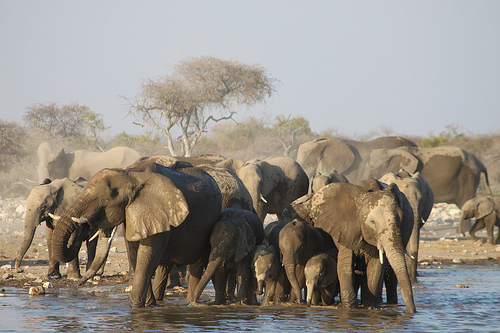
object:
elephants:
[289, 178, 420, 314]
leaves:
[157, 95, 173, 104]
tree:
[115, 55, 287, 158]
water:
[4, 262, 500, 333]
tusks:
[70, 216, 91, 226]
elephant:
[50, 160, 224, 307]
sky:
[0, 0, 500, 147]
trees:
[17, 101, 114, 143]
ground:
[0, 169, 500, 288]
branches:
[124, 113, 168, 132]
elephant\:
[191, 207, 266, 307]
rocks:
[25, 282, 49, 298]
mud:
[418, 258, 500, 268]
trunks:
[165, 126, 180, 157]